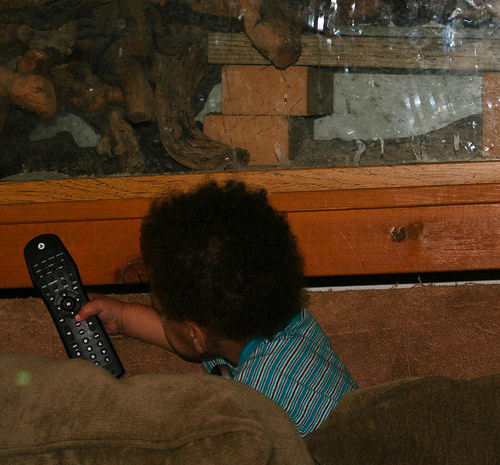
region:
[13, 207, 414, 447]
Boy with a remote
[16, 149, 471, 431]
Boy with a black remote.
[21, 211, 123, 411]
Black remote with white buttons.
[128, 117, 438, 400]
Boy with black hair.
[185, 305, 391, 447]
Striped shirt on the boy.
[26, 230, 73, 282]
Logo on the remote.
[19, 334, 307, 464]
Couch in the room.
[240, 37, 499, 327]
Wood in the background.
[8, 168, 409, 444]
Little boy on the couch.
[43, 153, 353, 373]
Little boy with a blue shirt.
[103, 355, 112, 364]
button on remote control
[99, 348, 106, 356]
button on remote control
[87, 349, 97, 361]
button on remote control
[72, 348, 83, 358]
button on remote control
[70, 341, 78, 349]
button on remote control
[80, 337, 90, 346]
button on remote control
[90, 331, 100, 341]
button on remote control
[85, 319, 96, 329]
button on remote control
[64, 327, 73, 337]
button on remote control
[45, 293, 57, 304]
button on remote control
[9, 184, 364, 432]
child holding a remote control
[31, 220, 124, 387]
black remote control with white numbers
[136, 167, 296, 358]
child with curly dark hair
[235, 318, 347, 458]
child wearing a blue striped shirt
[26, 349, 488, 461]
brown sofa cushions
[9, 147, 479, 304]
wooden frame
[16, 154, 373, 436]
small boy with one hand on remote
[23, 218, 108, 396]
remote in boys right hand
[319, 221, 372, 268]
scratch in the wood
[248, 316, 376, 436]
brown and white stripes on a blue shirt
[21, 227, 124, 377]
one black long remote control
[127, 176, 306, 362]
back of dark haired boy's head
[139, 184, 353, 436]
one boy wearing blue striped shirt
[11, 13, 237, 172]
group of bent wood logs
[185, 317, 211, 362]
one African American boy's left ear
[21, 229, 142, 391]
one child's hand holding TV remote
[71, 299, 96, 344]
one thumb on black remote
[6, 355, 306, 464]
top of brown sofa cushion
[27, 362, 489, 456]
tops of two brown couch cushions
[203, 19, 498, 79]
one piece of straight brown wood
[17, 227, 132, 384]
black remote control in child's hand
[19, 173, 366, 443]
child holding black remote control in hand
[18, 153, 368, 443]
child wearing blue striped shirt holding remote control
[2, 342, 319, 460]
brown pillow in front of child with remote control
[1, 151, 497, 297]
wood case behind child against the wall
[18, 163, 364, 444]
child with black hair holding black remote control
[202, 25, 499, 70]
wooden plank on top of brick blocks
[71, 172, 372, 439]
little child under brick blocks on wood frame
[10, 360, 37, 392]
green spot on brown pillow behind child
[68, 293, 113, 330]
child's thumb pressing button on the black remote control